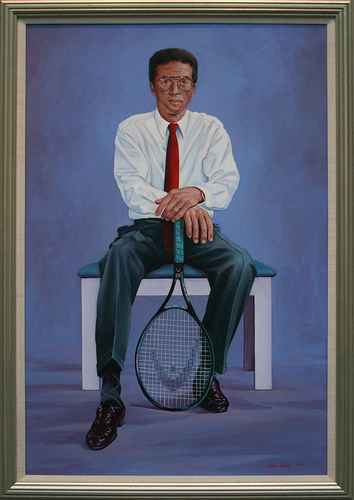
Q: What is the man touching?
A: A tennis racket.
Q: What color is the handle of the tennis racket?
A: Blue.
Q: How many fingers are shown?
A: Nine.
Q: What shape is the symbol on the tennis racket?
A: Parabola.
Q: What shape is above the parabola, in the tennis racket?
A: A solid circle.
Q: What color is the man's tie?
A: Red.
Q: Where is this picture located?
A: The picture frame.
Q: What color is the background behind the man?
A: Blue.